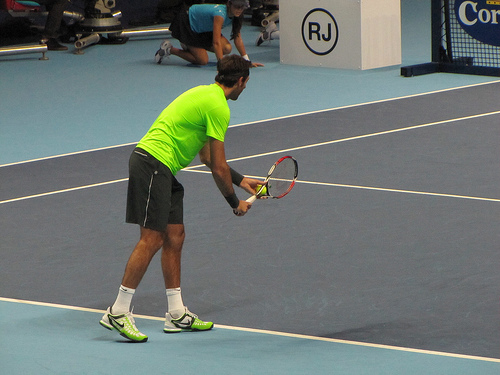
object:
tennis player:
[101, 54, 267, 342]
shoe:
[100, 306, 148, 341]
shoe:
[164, 306, 213, 333]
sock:
[112, 284, 136, 311]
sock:
[166, 287, 183, 312]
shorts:
[125, 148, 183, 232]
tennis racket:
[233, 156, 299, 215]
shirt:
[136, 84, 230, 177]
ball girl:
[154, 0, 263, 67]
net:
[447, 0, 498, 64]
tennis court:
[1, 0, 500, 374]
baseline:
[0, 80, 498, 167]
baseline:
[1, 291, 500, 364]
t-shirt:
[189, 4, 232, 33]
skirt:
[169, 5, 222, 47]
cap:
[228, 0, 250, 8]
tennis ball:
[257, 184, 267, 195]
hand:
[241, 177, 268, 199]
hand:
[235, 200, 251, 215]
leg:
[162, 183, 184, 288]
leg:
[121, 170, 164, 288]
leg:
[175, 44, 208, 65]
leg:
[206, 33, 232, 55]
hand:
[249, 63, 263, 68]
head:
[229, 0, 245, 17]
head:
[215, 54, 250, 100]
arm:
[200, 144, 243, 185]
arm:
[210, 117, 234, 196]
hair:
[215, 54, 251, 88]